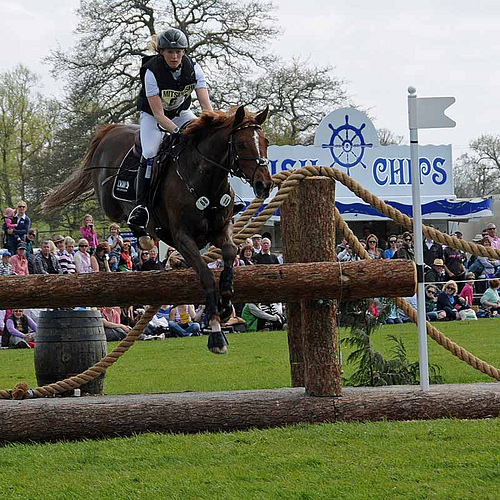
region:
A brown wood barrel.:
[32, 309, 108, 396]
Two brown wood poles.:
[0, 257, 499, 444]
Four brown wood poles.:
[0, 175, 499, 445]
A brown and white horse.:
[33, 103, 275, 355]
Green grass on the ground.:
[0, 317, 499, 499]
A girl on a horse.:
[126, 27, 217, 225]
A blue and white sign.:
[226, 105, 494, 227]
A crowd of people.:
[1, 198, 498, 350]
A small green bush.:
[338, 297, 447, 384]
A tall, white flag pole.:
[406, 83, 458, 391]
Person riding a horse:
[85, 23, 320, 353]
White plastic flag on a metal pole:
[389, 78, 484, 411]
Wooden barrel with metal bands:
[22, 289, 122, 411]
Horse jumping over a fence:
[60, 24, 294, 361]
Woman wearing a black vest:
[99, 24, 255, 236]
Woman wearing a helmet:
[90, 22, 247, 243]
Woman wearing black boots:
[101, 17, 236, 247]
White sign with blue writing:
[227, 91, 458, 220]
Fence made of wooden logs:
[0, 158, 435, 448]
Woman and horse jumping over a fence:
[28, 18, 324, 351]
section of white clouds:
[408, 42, 440, 65]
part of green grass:
[280, 460, 376, 480]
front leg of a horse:
[184, 237, 201, 264]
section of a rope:
[264, 205, 271, 218]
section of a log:
[313, 185, 327, 217]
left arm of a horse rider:
[153, 81, 163, 117]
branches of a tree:
[223, 33, 236, 51]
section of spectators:
[28, 230, 89, 262]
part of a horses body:
[185, 157, 222, 210]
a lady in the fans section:
[447, 277, 455, 297]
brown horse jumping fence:
[76, 99, 279, 333]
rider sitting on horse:
[129, 24, 214, 214]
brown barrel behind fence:
[29, 304, 111, 411]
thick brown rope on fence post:
[288, 163, 385, 220]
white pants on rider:
[128, 106, 210, 168]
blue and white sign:
[267, 137, 456, 204]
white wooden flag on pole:
[399, 82, 464, 214]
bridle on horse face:
[212, 125, 271, 194]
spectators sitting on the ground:
[107, 304, 208, 342]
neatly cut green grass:
[172, 357, 269, 385]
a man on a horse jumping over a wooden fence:
[36, 20, 288, 358]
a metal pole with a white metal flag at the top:
[400, 78, 475, 390]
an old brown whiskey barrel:
[23, 307, 114, 404]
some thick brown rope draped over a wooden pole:
[286, 165, 407, 234]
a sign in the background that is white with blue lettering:
[268, 106, 462, 210]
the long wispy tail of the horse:
[28, 130, 103, 220]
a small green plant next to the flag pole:
[343, 301, 420, 384]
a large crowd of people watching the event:
[3, 203, 166, 275]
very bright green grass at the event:
[249, 436, 482, 498]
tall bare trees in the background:
[211, 40, 339, 110]